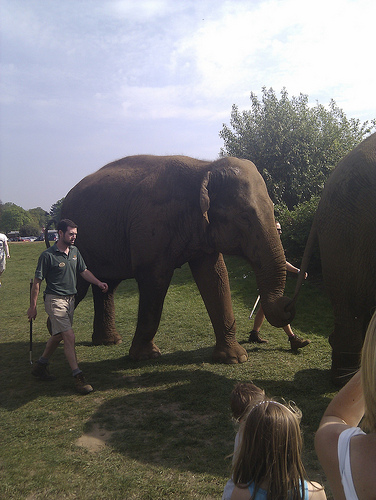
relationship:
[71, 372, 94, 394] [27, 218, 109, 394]
boot worn by man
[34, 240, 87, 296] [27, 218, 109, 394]
shirt worn man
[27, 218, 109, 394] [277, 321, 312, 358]
man wearing boot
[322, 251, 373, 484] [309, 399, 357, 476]
woman wearing garment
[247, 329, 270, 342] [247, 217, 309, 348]
boot worn by human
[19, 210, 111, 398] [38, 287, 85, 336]
man wearing shorts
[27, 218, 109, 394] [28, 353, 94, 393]
man wearing shoes